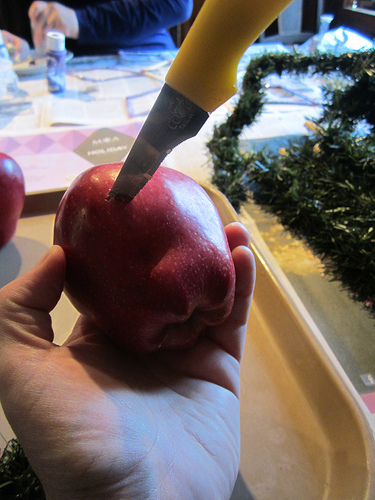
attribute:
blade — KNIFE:
[104, 84, 210, 206]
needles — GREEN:
[215, 55, 373, 314]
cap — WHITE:
[45, 30, 64, 51]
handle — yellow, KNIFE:
[164, 2, 296, 112]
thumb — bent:
[0, 244, 64, 395]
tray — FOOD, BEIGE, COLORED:
[9, 174, 372, 499]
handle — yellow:
[165, 0, 288, 120]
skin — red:
[131, 190, 182, 224]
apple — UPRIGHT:
[1, 146, 23, 256]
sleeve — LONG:
[65, 2, 193, 52]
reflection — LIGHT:
[156, 422, 206, 467]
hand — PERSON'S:
[1, 212, 287, 485]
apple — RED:
[43, 139, 247, 357]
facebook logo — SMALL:
[359, 370, 372, 388]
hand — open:
[0, 219, 257, 497]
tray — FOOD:
[22, 187, 49, 242]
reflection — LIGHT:
[166, 172, 227, 253]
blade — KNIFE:
[101, 108, 210, 203]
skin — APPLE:
[99, 205, 126, 214]